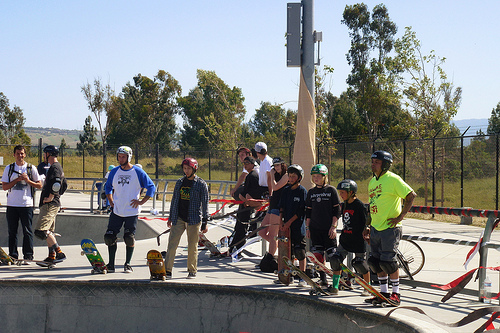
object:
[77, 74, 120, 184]
trees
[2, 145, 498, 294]
park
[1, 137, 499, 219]
fence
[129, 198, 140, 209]
hands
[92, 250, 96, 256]
wheels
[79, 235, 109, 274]
skateboard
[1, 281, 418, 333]
ramp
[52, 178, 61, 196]
pads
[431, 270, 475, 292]
streamer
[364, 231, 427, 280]
bicycle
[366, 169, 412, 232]
shirt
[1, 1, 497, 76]
sky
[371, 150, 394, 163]
helmet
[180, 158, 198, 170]
helmet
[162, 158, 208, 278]
skater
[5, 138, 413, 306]
group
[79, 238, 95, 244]
up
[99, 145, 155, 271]
man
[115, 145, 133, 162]
helmet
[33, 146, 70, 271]
person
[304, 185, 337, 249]
clothes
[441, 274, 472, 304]
streamer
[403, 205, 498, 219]
railing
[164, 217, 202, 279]
pants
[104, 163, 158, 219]
shirt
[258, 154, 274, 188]
shirt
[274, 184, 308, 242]
shirt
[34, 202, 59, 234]
shorts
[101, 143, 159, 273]
skateboarder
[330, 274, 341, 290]
socks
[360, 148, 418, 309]
people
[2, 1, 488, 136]
day